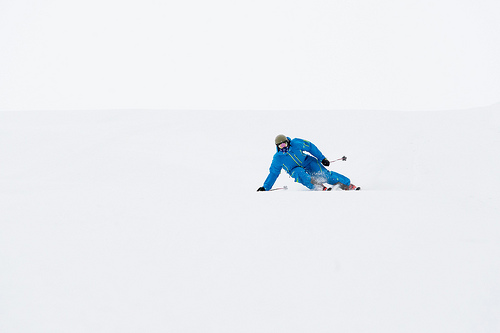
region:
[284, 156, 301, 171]
part of a blue jacket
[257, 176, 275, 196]
right hand of the skater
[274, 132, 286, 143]
part of a helmet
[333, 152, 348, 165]
part of a hooker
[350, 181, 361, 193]
part of the left skate board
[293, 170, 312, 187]
right leg of the skater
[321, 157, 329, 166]
part of a black glove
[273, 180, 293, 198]
part of a right hooker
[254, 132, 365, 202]
a skier traveling down a slope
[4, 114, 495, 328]
a solid white ski slope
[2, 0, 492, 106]
a snowy white sky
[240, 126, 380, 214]
a person in a blue snow suit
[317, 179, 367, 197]
a person's skis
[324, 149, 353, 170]
a person's ski poles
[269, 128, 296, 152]
a person wearing a helmet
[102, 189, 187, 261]
a solid patch of white snow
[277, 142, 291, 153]
a person's reflective glasses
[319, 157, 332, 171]
a person's black glove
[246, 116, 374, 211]
Skier wears a blue suit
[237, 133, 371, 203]
Skier go down the hill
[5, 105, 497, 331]
Hill is cover of snow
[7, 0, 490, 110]
Sky is cloudy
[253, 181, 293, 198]
Snow pole in right hand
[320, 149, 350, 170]
Snow pole in the left hand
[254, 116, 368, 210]
Person wears a green hat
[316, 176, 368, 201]
Skaters are orange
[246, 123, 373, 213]
Gloves of person are black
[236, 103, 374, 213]
Skater is leaning in the snow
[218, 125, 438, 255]
the man is skiing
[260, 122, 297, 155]
the person is wearing helmet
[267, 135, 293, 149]
the helmet is green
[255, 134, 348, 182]
the man is wearing a jacket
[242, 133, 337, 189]
the jacket is blue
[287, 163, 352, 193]
the pants is blue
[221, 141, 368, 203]
the man is wearing gloves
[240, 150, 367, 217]
the gloves are black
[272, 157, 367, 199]
the man is wearing pants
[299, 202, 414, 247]
the snow is white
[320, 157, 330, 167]
a black glove on the man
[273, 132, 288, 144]
a gray helmet on the man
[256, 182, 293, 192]
a ski pole in the man's hand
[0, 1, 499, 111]
a bright gray sky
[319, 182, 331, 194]
a red boot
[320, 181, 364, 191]
a pair of skis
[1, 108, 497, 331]
white snow on the ground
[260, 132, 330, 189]
a bright blue coat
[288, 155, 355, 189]
a bright blue pair of pants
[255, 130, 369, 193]
a man skiing